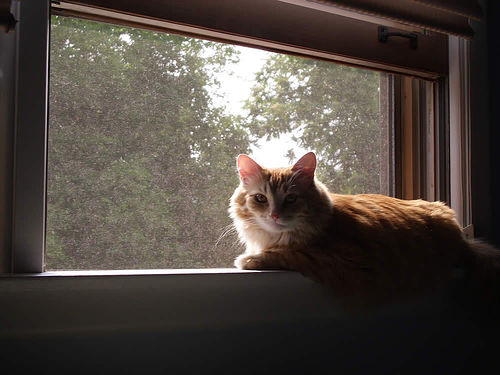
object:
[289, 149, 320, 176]
ear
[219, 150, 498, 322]
cat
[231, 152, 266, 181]
ear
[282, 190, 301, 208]
eye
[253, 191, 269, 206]
eye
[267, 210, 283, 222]
nose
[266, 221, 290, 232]
mouth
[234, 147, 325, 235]
head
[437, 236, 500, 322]
tail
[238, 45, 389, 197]
trees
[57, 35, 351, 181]
sky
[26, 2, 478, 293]
window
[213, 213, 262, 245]
whiskers